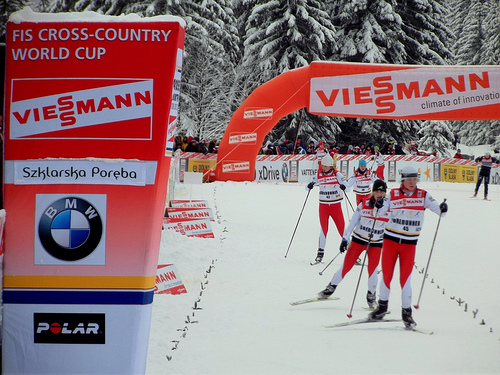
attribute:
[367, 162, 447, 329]
skier — racing, cross country, dressed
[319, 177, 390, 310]
skier — cross country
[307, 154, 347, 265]
skier — racing, cross country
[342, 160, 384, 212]
skier — dressed, racing, cross country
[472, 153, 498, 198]
skier — cross country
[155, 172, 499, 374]
snow — covereing, here, a thing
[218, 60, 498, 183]
sign — promotional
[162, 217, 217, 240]
advertisement — race, promotional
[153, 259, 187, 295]
advertisement — promotional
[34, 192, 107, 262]
advertisement — promotional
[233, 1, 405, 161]
tree — snowy, snow covered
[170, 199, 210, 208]
sign — white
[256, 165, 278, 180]
lettering — black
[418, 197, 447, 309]
ski pole — held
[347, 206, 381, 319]
ski pole — held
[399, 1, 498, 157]
tree — snow covered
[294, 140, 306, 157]
person — watching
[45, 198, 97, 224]
logo — bmw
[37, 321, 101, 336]
word — white, red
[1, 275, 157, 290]
stripe — yellow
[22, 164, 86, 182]
word — black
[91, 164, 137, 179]
word — black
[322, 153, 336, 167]
cap — white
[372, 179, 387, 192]
cap — black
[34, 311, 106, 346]
polar — sponsor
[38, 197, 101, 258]
bmw — sponsor